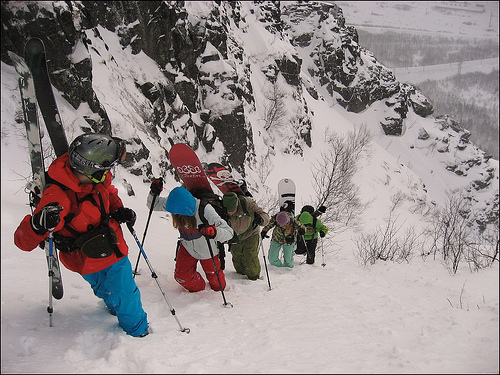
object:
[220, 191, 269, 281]
people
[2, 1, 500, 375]
mountain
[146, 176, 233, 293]
skier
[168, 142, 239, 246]
snowboard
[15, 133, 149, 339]
person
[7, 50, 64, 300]
skis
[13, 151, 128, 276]
parka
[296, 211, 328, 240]
coat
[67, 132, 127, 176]
helmet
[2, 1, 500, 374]
snow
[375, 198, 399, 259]
branches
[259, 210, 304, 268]
person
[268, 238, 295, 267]
pants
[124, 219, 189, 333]
ski pole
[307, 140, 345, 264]
brush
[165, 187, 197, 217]
hood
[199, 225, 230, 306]
ski poles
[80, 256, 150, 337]
pants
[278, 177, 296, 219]
snowboard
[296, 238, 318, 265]
pants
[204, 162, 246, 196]
board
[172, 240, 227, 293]
pants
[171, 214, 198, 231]
hair